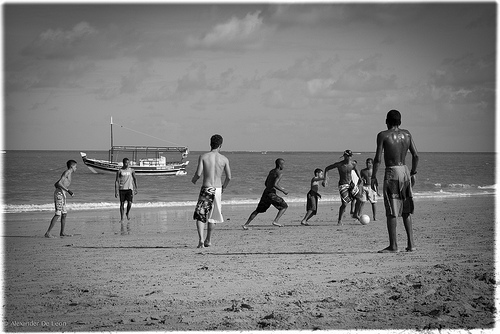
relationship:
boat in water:
[79, 112, 189, 177] [437, 150, 482, 180]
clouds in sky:
[24, 3, 495, 119] [7, 5, 494, 154]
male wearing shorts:
[241, 157, 289, 229] [255, 185, 287, 212]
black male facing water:
[370, 109, 421, 253] [5, 152, 491, 210]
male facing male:
[329, 143, 364, 223] [371, 101, 422, 252]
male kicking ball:
[329, 143, 364, 223] [357, 213, 372, 225]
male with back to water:
[176, 133, 238, 217] [189, 131, 363, 185]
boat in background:
[79, 112, 190, 186] [10, 3, 490, 195]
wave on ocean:
[7, 165, 497, 207] [3, 145, 498, 216]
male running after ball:
[240, 147, 295, 234] [358, 208, 375, 228]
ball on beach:
[354, 214, 381, 229] [10, 201, 491, 322]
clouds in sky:
[2, 3, 495, 152] [7, 5, 494, 154]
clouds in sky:
[2, 3, 495, 152] [78, 12, 497, 123]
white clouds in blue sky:
[168, 28, 301, 90] [133, 102, 198, 135]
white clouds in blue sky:
[301, 74, 351, 103] [7, 5, 497, 152]